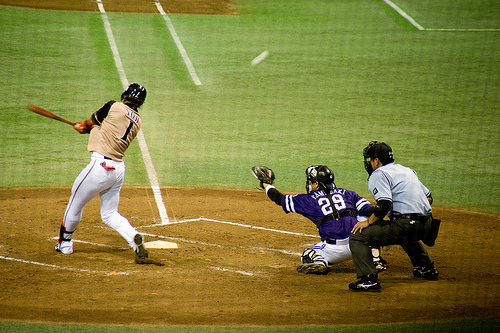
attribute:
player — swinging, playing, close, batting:
[69, 65, 152, 268]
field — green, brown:
[58, 16, 464, 157]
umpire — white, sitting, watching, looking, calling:
[357, 139, 450, 254]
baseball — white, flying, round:
[248, 41, 271, 77]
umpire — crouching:
[354, 148, 426, 291]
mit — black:
[238, 151, 273, 190]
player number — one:
[123, 120, 147, 150]